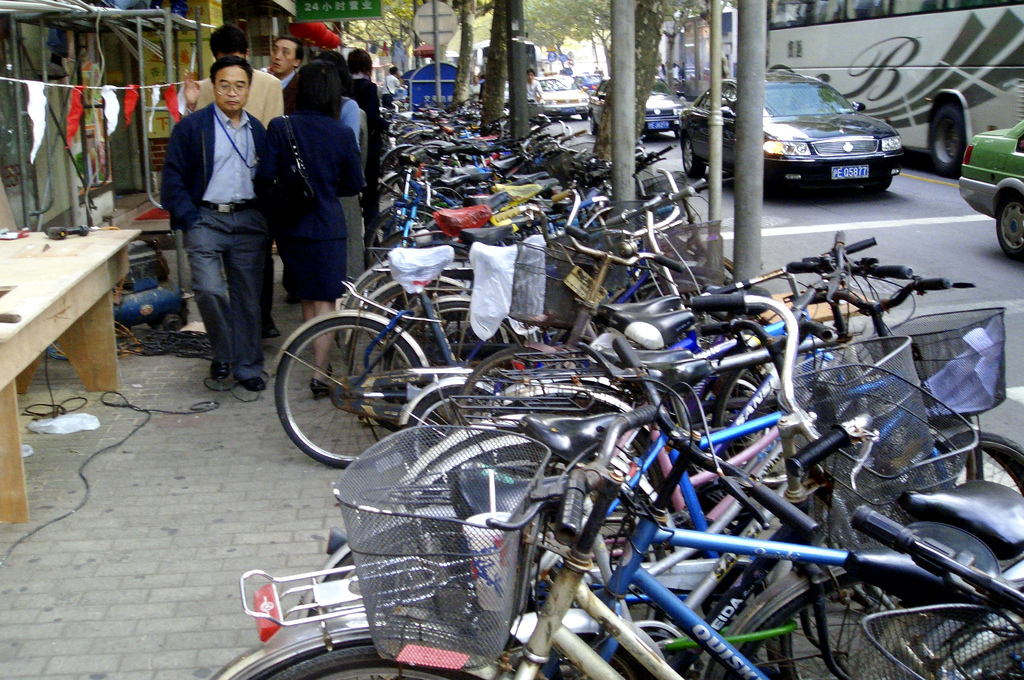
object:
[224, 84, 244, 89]
eyes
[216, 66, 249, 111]
face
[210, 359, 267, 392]
shoes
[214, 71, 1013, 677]
bicycles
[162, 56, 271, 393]
man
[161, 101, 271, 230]
jacket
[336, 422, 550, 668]
basket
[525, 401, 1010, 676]
bicycle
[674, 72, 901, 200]
car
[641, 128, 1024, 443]
road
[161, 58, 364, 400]
people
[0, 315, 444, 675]
sidewalk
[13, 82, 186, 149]
flags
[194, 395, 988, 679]
bicycle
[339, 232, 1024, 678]
bicycle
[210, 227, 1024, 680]
bicycle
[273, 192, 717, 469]
bicycle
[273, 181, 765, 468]
bicycle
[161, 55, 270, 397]
people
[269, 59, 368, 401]
people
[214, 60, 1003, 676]
line